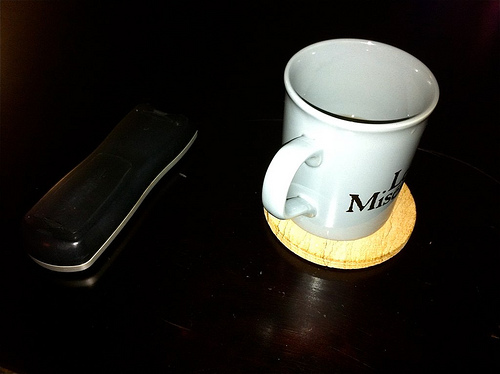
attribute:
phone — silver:
[3, 111, 243, 293]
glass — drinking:
[263, 37, 439, 239]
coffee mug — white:
[214, 42, 469, 260]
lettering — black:
[349, 167, 405, 212]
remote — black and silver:
[28, 91, 194, 277]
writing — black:
[348, 168, 410, 212]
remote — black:
[16, 93, 202, 278]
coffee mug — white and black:
[238, 29, 450, 252]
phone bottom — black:
[21, 98, 201, 287]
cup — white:
[250, 28, 450, 268]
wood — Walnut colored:
[240, 305, 492, 365]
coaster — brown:
[261, 181, 417, 271]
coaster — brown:
[295, 243, 387, 348]